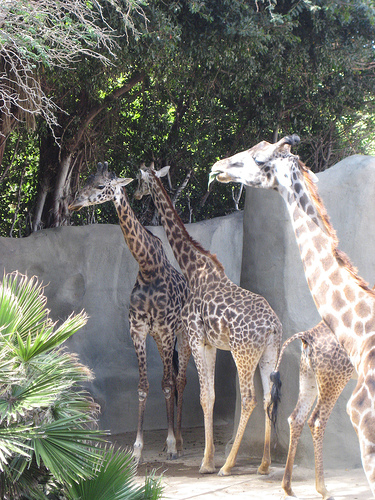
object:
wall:
[254, 94, 279, 110]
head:
[204, 115, 326, 208]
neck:
[264, 175, 373, 374]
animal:
[113, 170, 299, 458]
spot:
[205, 308, 222, 329]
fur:
[115, 197, 125, 213]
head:
[206, 135, 312, 198]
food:
[205, 170, 218, 189]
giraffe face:
[60, 157, 136, 214]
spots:
[132, 227, 171, 273]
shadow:
[117, 443, 273, 498]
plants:
[1, 266, 167, 498]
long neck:
[148, 180, 194, 257]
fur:
[163, 189, 191, 220]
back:
[221, 275, 264, 297]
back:
[312, 319, 325, 332]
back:
[168, 261, 181, 278]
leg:
[186, 332, 215, 471]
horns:
[271, 127, 296, 159]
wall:
[236, 150, 374, 472]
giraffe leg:
[188, 350, 212, 415]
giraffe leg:
[202, 348, 216, 382]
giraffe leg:
[158, 342, 173, 388]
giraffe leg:
[133, 349, 151, 394]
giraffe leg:
[235, 364, 259, 414]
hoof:
[211, 467, 234, 478]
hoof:
[253, 462, 272, 480]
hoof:
[195, 458, 219, 474]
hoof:
[129, 448, 150, 467]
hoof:
[162, 445, 177, 463]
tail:
[265, 366, 282, 430]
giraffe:
[203, 119, 371, 497]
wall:
[142, 59, 167, 77]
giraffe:
[208, 110, 363, 261]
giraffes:
[2, 95, 373, 490]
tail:
[264, 330, 308, 437]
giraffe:
[264, 318, 360, 499]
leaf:
[205, 165, 217, 185]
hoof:
[278, 480, 293, 496]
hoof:
[315, 481, 332, 498]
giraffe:
[65, 154, 193, 479]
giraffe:
[132, 148, 283, 476]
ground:
[123, 433, 349, 498]